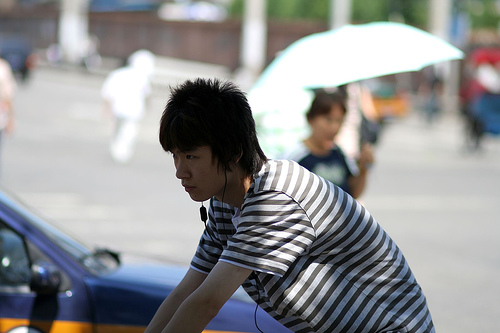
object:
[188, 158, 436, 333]
shirt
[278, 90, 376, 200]
person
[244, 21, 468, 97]
umbrella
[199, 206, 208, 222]
volume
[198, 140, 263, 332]
headphones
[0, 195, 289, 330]
car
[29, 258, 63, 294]
mirror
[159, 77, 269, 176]
hair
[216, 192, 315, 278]
sleeve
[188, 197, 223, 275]
sleeve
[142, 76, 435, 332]
guy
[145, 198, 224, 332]
arm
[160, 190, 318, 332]
arm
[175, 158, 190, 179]
nose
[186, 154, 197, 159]
eye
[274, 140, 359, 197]
shirt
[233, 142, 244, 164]
ear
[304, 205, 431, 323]
shadow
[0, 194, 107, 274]
windshield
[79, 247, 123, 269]
wiper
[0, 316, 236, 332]
line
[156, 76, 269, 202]
head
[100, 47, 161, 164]
person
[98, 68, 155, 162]
suit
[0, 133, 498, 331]
street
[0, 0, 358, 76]
fence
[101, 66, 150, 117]
shirt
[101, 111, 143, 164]
pants